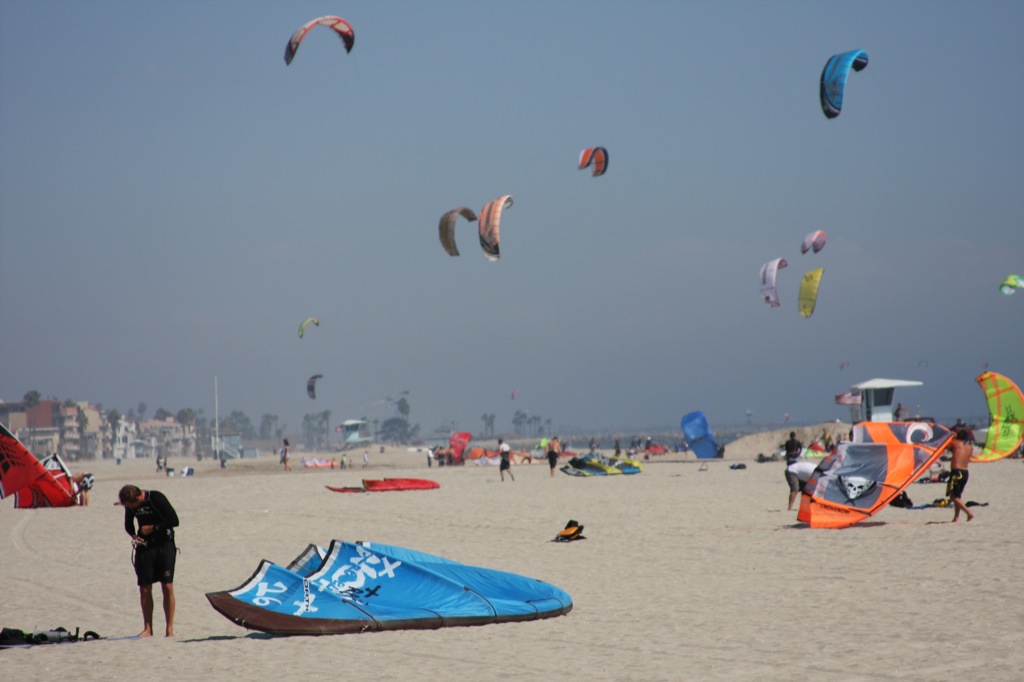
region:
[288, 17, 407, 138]
kite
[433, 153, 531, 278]
kites in air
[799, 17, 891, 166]
blue kite in air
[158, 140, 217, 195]
white clouds in blue sky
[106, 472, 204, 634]
man in black wet suit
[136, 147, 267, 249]
white clouds in blue sky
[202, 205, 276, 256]
white clouds in blue sky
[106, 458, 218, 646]
The man wearing black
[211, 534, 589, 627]
A blue parachute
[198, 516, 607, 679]
The blue parachute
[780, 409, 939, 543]
The orange parachute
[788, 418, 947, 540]
An orange parachute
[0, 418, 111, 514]
The red parachute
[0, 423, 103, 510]
A red parachute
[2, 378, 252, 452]
A set of buildings on the horizon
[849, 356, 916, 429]
The white lifeguard stand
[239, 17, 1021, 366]
The different color parachutes in the sky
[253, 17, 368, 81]
kite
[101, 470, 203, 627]
man with black wet suit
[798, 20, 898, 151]
large blue kite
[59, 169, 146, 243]
white clouds in the blue sky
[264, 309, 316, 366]
white clouds in the blue sky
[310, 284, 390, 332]
white clouds in the blue sky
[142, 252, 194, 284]
white clouds in the blue sky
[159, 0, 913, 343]
the kites are flying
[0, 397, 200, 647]
the man is looking down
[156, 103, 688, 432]
the sky is overcast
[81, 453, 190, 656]
the man is standing in the sand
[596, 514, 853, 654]
the sand is beige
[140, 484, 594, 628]
the kite is blue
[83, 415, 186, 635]
the man is wearing all black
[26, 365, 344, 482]
buildings in the background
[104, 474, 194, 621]
man wearing black wet suit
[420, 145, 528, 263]
kites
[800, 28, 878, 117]
kite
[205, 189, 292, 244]
white clouds in blue sky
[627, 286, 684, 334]
white clouds in the blue sky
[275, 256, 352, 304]
white clouds in the blue sky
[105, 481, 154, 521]
the head of a man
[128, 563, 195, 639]
the legs of a man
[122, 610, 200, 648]
the feet of a man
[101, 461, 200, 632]
man wearing black shorts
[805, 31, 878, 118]
blue and black kite in the sky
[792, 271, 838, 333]
yellow kite in the sky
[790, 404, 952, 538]
gray and orange kite on the sand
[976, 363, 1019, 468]
orange and neon yellow kite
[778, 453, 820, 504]
man wearing white shirt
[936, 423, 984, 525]
man wearing black shorts with yellow stripe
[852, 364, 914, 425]
white lifeguard stand on the sand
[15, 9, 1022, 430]
blue gray sky above the sand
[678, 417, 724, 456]
blue kite on the sand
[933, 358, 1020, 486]
a person on the beach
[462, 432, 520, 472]
a person on the beach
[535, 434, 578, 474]
a person on the beach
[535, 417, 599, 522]
a person on the beach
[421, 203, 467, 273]
a parasail in the sky